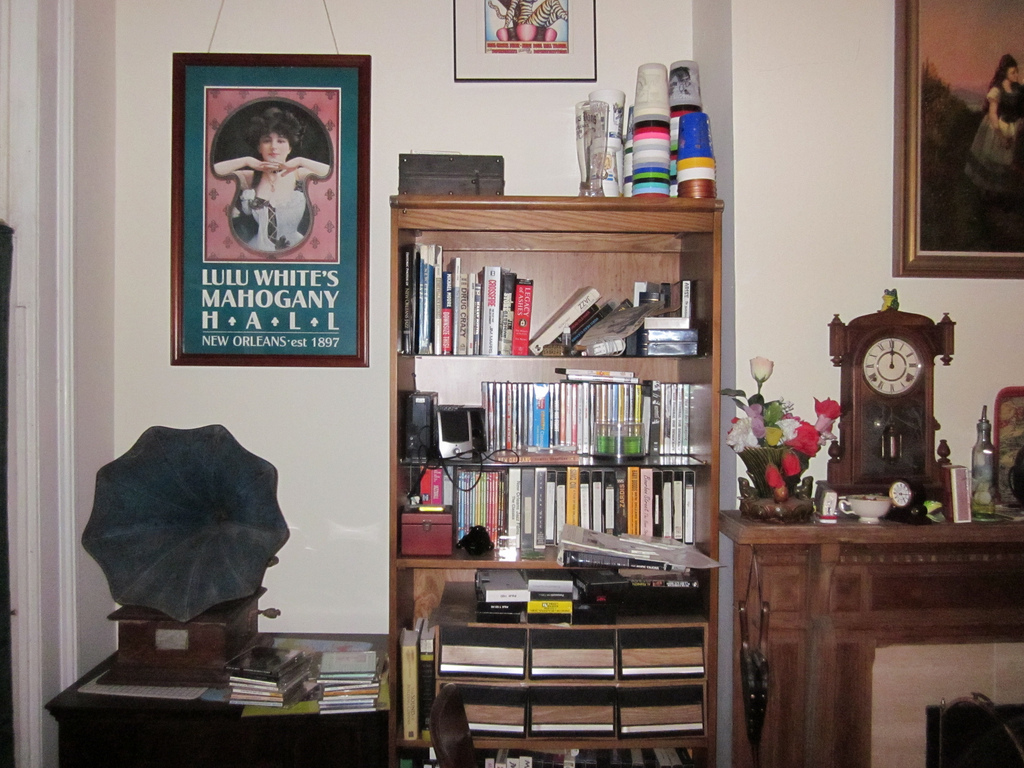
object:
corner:
[99, 4, 131, 658]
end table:
[42, 631, 394, 768]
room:
[0, 0, 1024, 768]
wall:
[110, 0, 695, 638]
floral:
[714, 355, 846, 524]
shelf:
[392, 451, 708, 470]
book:
[672, 479, 683, 544]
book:
[478, 265, 501, 356]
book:
[498, 272, 518, 356]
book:
[528, 285, 603, 356]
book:
[418, 245, 424, 356]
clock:
[813, 287, 957, 516]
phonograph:
[79, 423, 292, 690]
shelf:
[39, 630, 405, 730]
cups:
[673, 112, 721, 165]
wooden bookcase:
[381, 197, 722, 768]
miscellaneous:
[403, 235, 712, 768]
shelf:
[392, 546, 714, 570]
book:
[510, 279, 535, 357]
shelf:
[396, 356, 715, 370]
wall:
[725, 0, 1024, 514]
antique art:
[169, 53, 369, 369]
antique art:
[892, 0, 1024, 280]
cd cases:
[618, 683, 706, 744]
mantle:
[717, 502, 1018, 530]